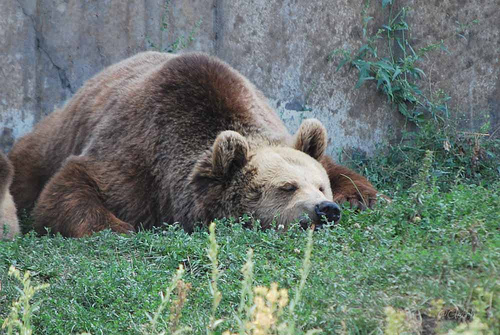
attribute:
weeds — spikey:
[335, 0, 447, 145]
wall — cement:
[218, 2, 496, 139]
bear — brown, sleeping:
[0, 50, 394, 237]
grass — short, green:
[2, 235, 493, 335]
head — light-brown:
[211, 117, 337, 231]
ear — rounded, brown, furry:
[296, 117, 328, 162]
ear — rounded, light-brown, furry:
[212, 129, 248, 183]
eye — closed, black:
[279, 183, 298, 193]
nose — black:
[315, 201, 341, 225]